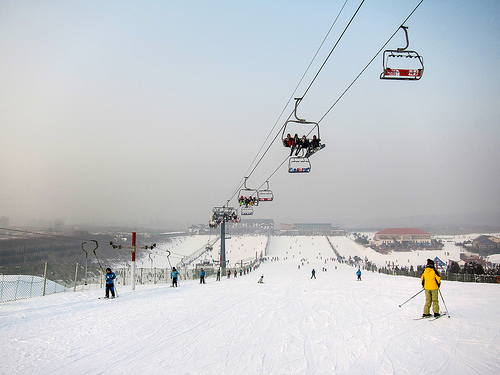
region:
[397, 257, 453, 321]
skier wearing a yellow jacket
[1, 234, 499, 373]
smooth run of snow for skiing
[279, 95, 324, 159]
open air chair lift with four passengers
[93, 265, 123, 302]
skier in a blue coat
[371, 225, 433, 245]
large tan building with a red roof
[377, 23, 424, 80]
empty open air ski lift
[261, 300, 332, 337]
the snow is white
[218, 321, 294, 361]
the white snow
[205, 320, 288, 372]
the snow is white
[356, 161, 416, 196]
a cloudy sky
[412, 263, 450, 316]
a person skiing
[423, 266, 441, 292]
a yellow sweater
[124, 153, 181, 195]
the sky is grey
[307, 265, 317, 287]
people skiing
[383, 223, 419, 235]
a building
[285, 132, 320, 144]
people seating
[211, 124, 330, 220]
Cars on a ski resort chairlift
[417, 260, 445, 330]
A skier with a yellow parka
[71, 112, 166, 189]
A gray empty sky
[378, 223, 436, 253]
A distant building with trees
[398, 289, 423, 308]
An extended ski pole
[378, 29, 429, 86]
An empty chair on a ski lift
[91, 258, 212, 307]
Several skiers working up a hill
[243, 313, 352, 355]
An area of clear white snow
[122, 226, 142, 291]
A red and white pole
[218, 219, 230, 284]
A tall gray metal pole support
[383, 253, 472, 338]
person in yellow jacket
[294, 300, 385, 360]
white snow on ground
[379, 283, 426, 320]
ski pole in person's hand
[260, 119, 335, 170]
people above the snow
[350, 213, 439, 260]
building in the distance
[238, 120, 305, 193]
wires above the land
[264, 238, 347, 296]
people in the distance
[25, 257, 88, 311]
fence next to people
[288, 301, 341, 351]
the white snow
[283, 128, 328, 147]
people sitting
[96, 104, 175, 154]
the sky is cloudy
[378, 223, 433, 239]
a building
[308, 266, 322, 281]
a person skiing in the snow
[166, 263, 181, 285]
a person wearing blue and black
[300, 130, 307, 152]
skier on the chair lift going up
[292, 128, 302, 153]
skier on the chair lift going up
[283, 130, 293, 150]
skier on the chair lift going up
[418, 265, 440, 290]
A skier wearing a yellow jacket.